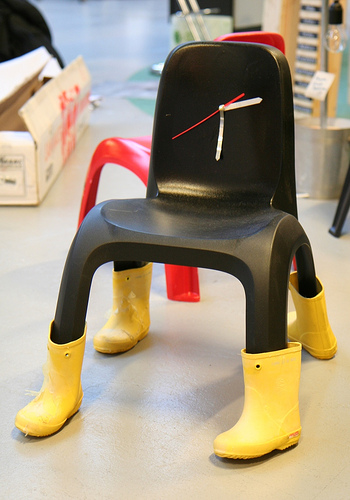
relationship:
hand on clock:
[218, 99, 269, 112] [195, 85, 253, 163]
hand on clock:
[210, 119, 225, 166] [195, 85, 253, 163]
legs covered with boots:
[14, 248, 338, 470] [11, 263, 336, 461]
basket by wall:
[294, 116, 348, 198] [306, 27, 348, 175]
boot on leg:
[285, 270, 339, 362] [293, 240, 317, 297]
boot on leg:
[212, 338, 302, 459] [245, 276, 288, 352]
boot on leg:
[94, 260, 153, 354] [114, 259, 145, 272]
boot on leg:
[12, 316, 87, 437] [53, 249, 93, 345]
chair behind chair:
[13, 38, 341, 464] [13, 35, 339, 463]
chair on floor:
[13, 35, 339, 463] [3, 256, 349, 498]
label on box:
[41, 85, 89, 162] [0, 45, 89, 205]